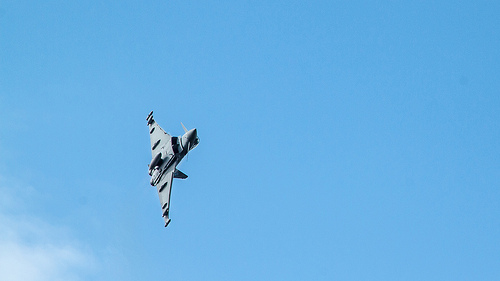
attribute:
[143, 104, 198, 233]
jet — flying, grey, tilted, military, silver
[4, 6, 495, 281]
sky — blue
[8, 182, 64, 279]
cloud — white